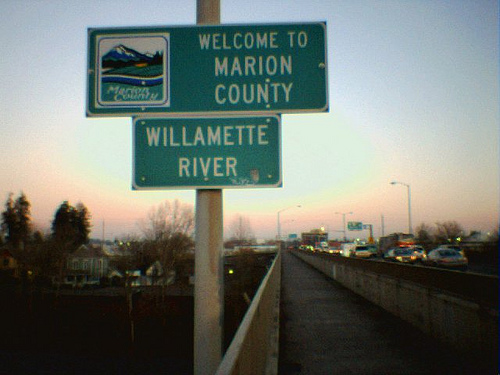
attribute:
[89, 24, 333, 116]
sign — green, top, gree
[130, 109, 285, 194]
sign — green, bottom, gree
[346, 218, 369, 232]
sign — green, suspended, far, gree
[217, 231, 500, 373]
bridge — long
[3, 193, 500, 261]
horizon — pink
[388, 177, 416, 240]
street light — tall, far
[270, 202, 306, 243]
street light — tall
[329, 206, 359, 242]
street light — tall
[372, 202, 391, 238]
street light — tall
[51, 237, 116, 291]
house — riverside, far, gray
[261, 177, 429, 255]
street lights — on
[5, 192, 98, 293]
trees — pine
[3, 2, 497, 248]
sky — far, blue, red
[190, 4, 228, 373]
post — metal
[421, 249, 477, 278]
car — black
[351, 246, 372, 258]
seda — small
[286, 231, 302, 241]
sign — far